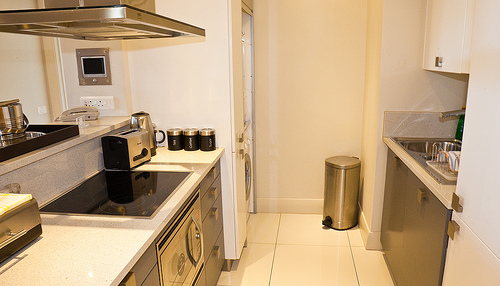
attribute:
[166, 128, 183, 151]
canister — silver, black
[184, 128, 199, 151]
canister — silver, black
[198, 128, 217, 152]
canister — silver, black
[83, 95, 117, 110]
outlets — white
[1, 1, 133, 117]
wall — white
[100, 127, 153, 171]
toaster — black, silver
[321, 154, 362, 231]
trash can — silver, metal, stainless steel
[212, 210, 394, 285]
floor — white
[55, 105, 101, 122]
phone — white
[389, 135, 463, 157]
sink — silver